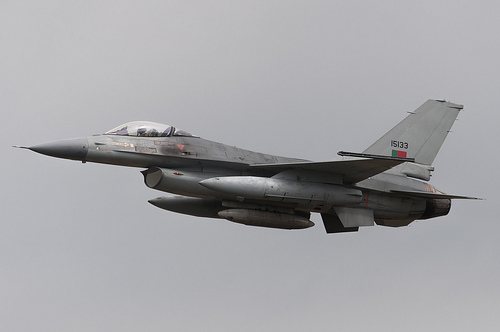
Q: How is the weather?
A: It is overcast.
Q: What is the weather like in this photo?
A: It is overcast.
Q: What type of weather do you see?
A: It is overcast.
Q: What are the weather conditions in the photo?
A: It is overcast.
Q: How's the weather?
A: It is overcast.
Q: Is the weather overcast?
A: Yes, it is overcast.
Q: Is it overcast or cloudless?
A: It is overcast.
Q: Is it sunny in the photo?
A: No, it is overcast.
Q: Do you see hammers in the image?
A: No, there are no hammers.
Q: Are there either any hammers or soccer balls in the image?
A: No, there are no hammers or soccer balls.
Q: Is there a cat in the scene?
A: No, there are no cats.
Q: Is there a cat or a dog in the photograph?
A: No, there are no cats or dogs.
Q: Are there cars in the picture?
A: No, there are no cars.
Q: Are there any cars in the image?
A: No, there are no cars.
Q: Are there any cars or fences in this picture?
A: No, there are no cars or fences.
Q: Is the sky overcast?
A: Yes, the sky is overcast.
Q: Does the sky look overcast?
A: Yes, the sky is overcast.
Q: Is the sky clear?
A: No, the sky is overcast.